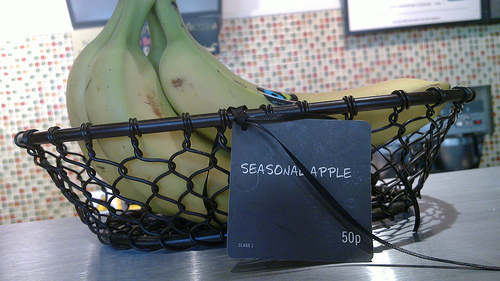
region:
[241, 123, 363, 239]
this is a card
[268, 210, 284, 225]
the card is black in color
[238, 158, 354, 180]
these are some writings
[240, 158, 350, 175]
the writings are in white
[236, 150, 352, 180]
the writings are in bold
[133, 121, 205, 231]
this is a basket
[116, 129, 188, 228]
the basket is metallic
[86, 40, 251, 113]
these are some bananas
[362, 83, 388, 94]
the bananas are yellow in color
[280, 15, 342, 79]
this is the wall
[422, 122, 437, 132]
part of a basket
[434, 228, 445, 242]
part of a table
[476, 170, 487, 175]
edge of a table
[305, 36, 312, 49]
side of a wall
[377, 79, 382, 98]
part of a basket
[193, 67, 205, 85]
part of a banana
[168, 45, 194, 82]
edge of a banana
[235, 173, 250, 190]
part of a label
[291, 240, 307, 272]
edge of a label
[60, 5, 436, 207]
a "bunch" of bananas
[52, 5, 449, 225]
several ripe bananas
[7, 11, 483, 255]
bananas in a fruit basket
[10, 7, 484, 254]
bananas in the wrong basket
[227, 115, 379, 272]
advertisement for apples for 50p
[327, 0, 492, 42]
display screen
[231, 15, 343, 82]
decorative pattern tiling on the wall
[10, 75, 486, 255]
a basket for fruits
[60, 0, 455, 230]
bunch of four bananas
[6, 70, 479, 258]
a metal fruit basket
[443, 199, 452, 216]
part of a table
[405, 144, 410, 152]
part of a basket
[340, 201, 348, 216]
part of a paper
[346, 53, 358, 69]
part of a wall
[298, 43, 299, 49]
edge of a wall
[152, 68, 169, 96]
part of a banana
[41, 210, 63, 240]
part of a table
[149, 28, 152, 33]
part of a banana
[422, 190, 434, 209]
edge of a table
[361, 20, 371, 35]
part of a painting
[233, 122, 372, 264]
black seasonal apple sign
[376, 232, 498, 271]
long black string on basket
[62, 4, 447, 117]
set of yellow banannas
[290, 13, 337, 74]
checkered pattern on wall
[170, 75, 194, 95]
brown bruise on bananna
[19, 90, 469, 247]
black basket holding banannas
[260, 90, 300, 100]
black sticker on banana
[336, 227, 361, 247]
50 p printed on sign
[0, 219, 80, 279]
grey table holding basket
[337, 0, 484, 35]
black flatscreen tv on wall